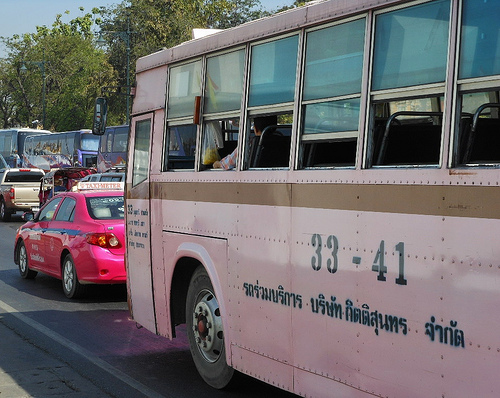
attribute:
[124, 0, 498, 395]
bus — white, pink, large, foreign, not a trck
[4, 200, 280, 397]
street — black, concrete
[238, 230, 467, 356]
writing — foreign, green, asian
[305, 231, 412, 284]
33-41 — numbers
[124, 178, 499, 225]
gold stripe — brown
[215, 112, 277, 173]
person — riding in bus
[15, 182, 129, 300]
taxi — red, car, pink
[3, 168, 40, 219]
truck — gold, white, brown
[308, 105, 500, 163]
seats — empty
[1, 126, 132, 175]
buses — parked, 3, commercial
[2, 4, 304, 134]
trees — tall, green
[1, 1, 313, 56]
sky — clear, blue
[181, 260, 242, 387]
tire — black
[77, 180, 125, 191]
sign — white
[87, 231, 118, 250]
rear lights — red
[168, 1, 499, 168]
windows — open